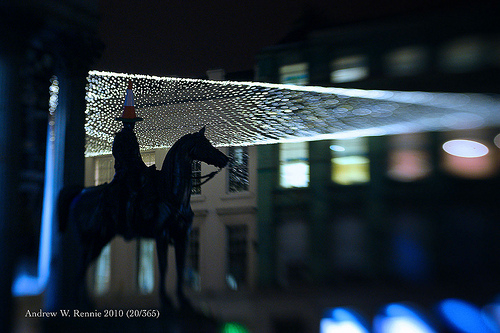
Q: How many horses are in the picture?
A: 1.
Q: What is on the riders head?
A: A cone.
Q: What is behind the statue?
A: Buildings.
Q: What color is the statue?
A: Black.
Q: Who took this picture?
A: Andrew W. Rennie.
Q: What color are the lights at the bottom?
A: Blue.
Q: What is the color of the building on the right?
A: Green.